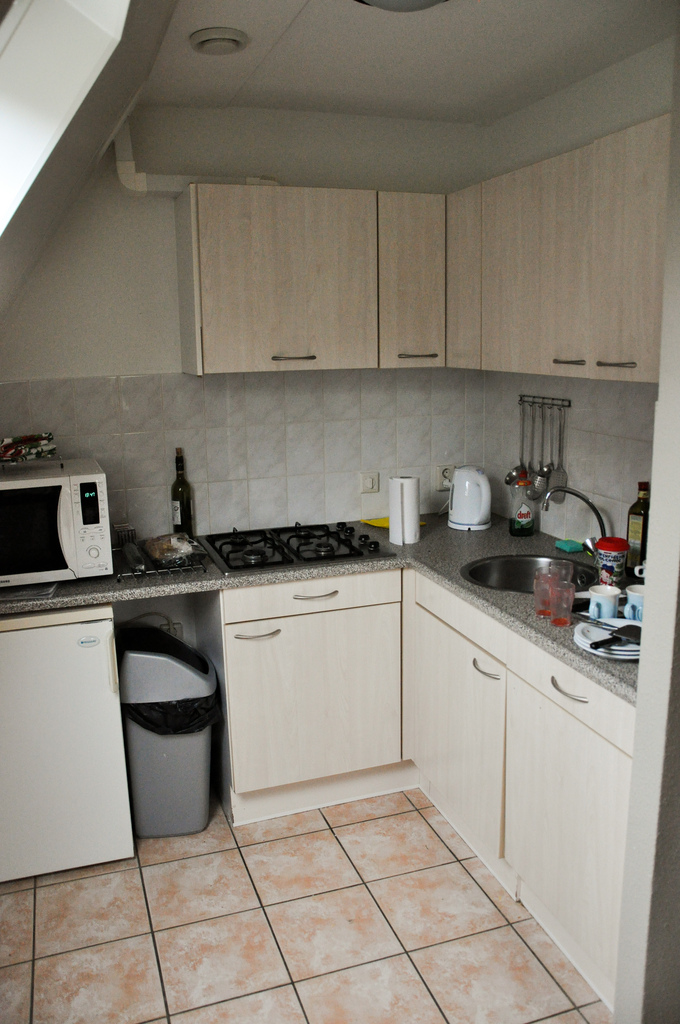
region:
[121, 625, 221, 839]
a grey covered trash can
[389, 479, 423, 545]
a roll of paper towels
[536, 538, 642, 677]
a lot dirty dishes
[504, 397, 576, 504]
a rack of cooking utinsils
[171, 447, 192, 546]
a green wine bottle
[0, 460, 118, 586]
a microwave oven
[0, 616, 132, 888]
a small refridgerator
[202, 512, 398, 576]
a gas four burner cooktop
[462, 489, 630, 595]
a chrome kitchen sink and faucet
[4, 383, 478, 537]
a white tiled backsplash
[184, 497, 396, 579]
A gas range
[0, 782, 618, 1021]
orange and white mottled tile floor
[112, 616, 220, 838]
gray trash can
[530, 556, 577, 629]
empty drinking glasses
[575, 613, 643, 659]
stack of empty plates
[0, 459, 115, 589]
white microwave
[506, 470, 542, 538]
almost empty bottle of dish soap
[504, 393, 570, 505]
metal utensils hanging on wall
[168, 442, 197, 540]
corked bottle of wine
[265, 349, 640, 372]
arched metal cabinet handles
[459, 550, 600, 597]
round sink basin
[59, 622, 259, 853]
A garbage can on the floor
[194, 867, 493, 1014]
Big tiles on kitchen floor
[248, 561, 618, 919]
Cabinets are white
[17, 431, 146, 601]
A microwave is white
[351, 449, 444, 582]
A roll of paper towels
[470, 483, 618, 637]
Faucet and sink is silver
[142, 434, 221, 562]
A bottle of wine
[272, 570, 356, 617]
Silver handle on a drawer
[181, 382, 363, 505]
Tiles on a wall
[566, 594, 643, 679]
Round white plates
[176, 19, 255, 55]
smoke detector on the ceiling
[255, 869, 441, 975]
peach and white tiles on the ground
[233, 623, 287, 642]
silver handles on cabinets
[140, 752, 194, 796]
a grey wastepaper basket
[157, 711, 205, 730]
a black trash bag in the trash can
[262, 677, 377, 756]
cabinets are white with wood grain faintly visible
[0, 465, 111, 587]
a microwave on a countertop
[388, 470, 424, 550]
roll of paper towels on countertop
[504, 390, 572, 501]
cooking utensils hanging from the wall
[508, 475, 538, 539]
container of dish-washing liquid near the sink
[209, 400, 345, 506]
White tiles on the wall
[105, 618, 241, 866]
A gray garbage can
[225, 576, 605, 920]
The cabinets and drawers are white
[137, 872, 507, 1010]
Large tiles are on the floor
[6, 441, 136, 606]
The microwave is white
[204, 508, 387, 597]
The gas stove is black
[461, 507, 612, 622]
The sink is silver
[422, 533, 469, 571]
The countertop is gray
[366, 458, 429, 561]
White paper towels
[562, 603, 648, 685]
White plates stacked on each other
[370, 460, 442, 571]
White roll of paper towels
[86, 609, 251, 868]
Garbage can on the floor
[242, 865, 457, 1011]
Tiles on kitchen floor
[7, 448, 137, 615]
A white microwave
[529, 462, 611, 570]
The faucet is silver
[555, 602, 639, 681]
Plates stacked on top of each other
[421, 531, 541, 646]
The countertop is gray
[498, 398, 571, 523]
Utensils hanging on the wall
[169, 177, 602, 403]
Cabinets are cream colored